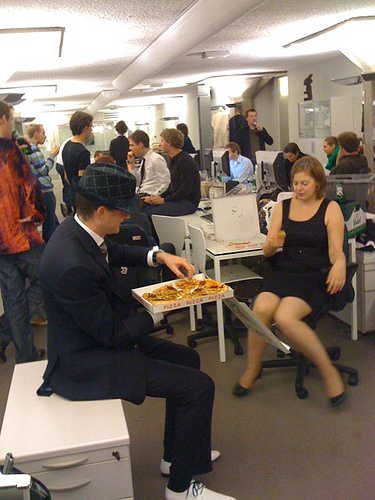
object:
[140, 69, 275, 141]
wall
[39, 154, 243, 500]
guy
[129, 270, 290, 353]
box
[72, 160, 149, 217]
hat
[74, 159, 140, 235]
head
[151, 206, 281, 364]
desk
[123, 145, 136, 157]
pizza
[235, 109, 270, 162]
guy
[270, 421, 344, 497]
ground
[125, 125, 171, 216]
guy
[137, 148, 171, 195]
dress shirt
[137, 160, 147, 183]
tie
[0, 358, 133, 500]
cabinet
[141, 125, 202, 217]
man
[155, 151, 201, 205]
black shirt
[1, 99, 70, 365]
standing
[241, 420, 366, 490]
floor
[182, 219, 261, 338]
chairs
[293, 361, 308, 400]
office chair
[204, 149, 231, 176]
computer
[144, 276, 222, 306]
pizza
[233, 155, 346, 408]
lady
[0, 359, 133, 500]
trunk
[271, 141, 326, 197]
man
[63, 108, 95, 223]
man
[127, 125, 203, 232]
two men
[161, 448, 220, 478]
shoes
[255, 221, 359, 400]
chair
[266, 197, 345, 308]
dress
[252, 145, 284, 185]
screen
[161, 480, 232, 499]
shoes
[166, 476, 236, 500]
feet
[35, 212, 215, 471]
suit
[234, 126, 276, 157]
coat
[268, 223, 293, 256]
pizza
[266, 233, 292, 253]
hand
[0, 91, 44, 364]
people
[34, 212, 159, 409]
jacket